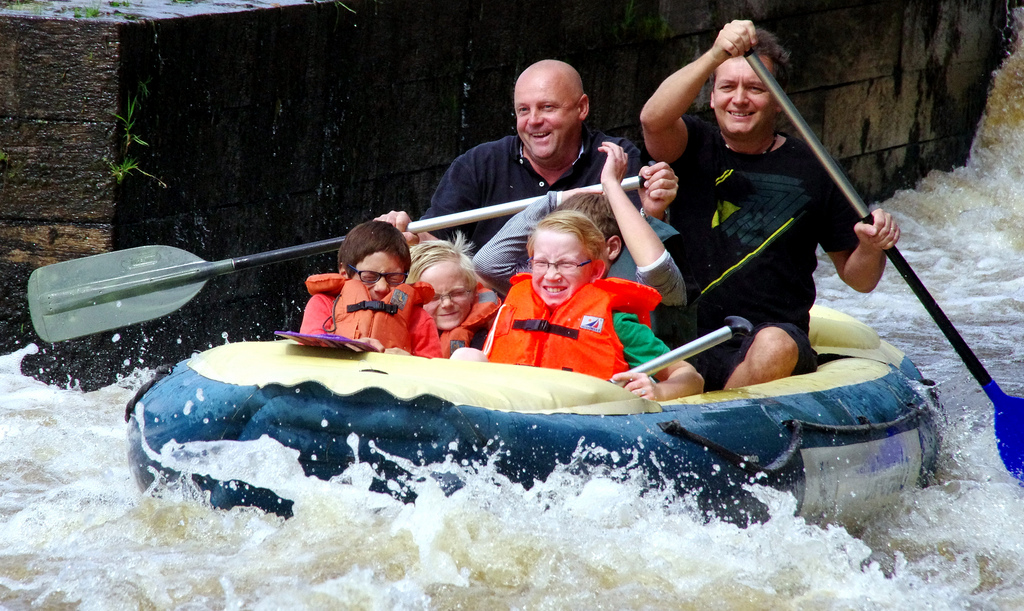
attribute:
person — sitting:
[407, 241, 500, 352]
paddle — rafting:
[741, 37, 1023, 483]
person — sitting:
[378, 56, 679, 252]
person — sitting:
[637, 15, 904, 393]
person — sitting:
[299, 219, 443, 357]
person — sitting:
[489, 214, 705, 401]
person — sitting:
[470, 138, 692, 307]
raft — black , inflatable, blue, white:
[125, 301, 947, 539]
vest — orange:
[485, 270, 663, 384]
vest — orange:
[438, 282, 503, 360]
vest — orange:
[306, 269, 434, 355]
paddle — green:
[27, 176, 644, 344]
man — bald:
[380, 58, 681, 249]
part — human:
[501, 57, 590, 167]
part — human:
[333, 218, 400, 299]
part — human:
[409, 237, 480, 336]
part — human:
[531, 215, 602, 307]